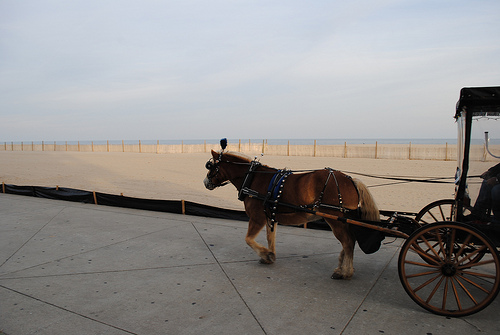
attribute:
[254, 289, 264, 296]
dot — black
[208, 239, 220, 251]
dot — black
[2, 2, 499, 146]
sky — cloudy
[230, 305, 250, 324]
dot — black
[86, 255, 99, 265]
dot — black